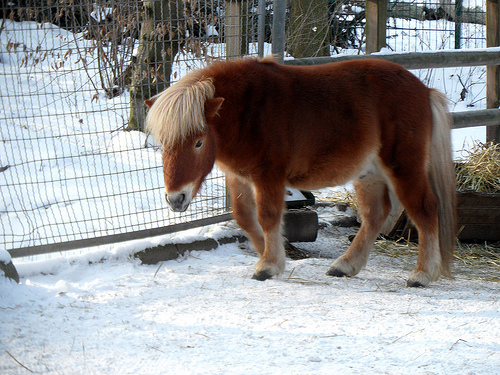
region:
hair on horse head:
[141, 77, 216, 148]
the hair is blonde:
[141, 75, 211, 145]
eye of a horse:
[193, 138, 203, 147]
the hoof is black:
[254, 268, 271, 280]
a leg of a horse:
[377, 135, 442, 288]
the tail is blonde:
[428, 90, 456, 281]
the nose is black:
[163, 193, 186, 206]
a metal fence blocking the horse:
[2, 0, 486, 259]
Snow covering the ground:
[0, 18, 498, 373]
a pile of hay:
[460, 139, 499, 193]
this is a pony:
[118, 52, 497, 260]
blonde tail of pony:
[420, 82, 487, 282]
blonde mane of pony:
[122, 71, 228, 156]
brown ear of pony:
[188, 87, 236, 123]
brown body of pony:
[166, 51, 473, 261]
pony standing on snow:
[128, 42, 478, 321]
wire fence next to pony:
[15, 28, 246, 236]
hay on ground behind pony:
[405, 99, 497, 245]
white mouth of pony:
[135, 176, 213, 230]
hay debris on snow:
[57, 282, 314, 372]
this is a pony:
[168, 98, 348, 192]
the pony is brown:
[113, 78, 415, 283]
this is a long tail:
[407, 105, 474, 197]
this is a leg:
[138, 196, 345, 328]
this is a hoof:
[230, 258, 267, 291]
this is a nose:
[113, 162, 248, 257]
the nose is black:
[166, 178, 185, 203]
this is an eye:
[155, 131, 260, 158]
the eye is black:
[138, 120, 245, 212]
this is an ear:
[143, 85, 237, 142]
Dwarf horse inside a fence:
[141, 54, 461, 288]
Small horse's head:
[142, 71, 229, 213]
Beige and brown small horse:
[139, 55, 465, 287]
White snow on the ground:
[117, 291, 344, 361]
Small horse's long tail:
[426, 85, 465, 284]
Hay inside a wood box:
[456, 135, 499, 243]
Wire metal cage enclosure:
[11, 84, 101, 214]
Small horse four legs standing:
[248, 243, 442, 290]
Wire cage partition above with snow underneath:
[19, 223, 138, 268]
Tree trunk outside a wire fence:
[116, 3, 188, 77]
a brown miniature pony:
[145, 58, 457, 291]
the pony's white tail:
[430, 93, 457, 273]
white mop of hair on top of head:
[142, 81, 210, 142]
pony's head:
[144, 95, 218, 207]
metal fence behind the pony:
[0, 5, 498, 223]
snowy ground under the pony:
[16, 253, 498, 366]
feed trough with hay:
[406, 144, 497, 236]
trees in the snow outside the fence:
[62, 3, 328, 129]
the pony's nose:
[163, 191, 188, 209]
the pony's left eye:
[195, 140, 203, 151]